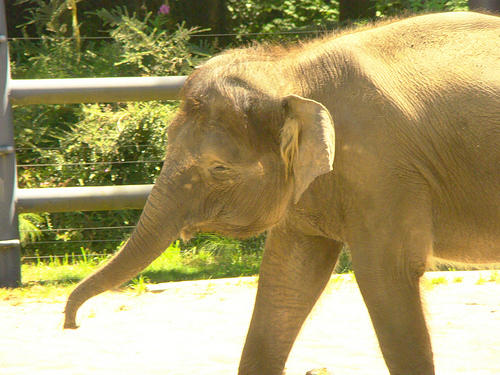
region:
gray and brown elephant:
[40, 20, 480, 370]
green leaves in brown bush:
[88, 110, 132, 135]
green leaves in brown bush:
[116, 126, 148, 146]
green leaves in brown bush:
[57, 220, 106, 249]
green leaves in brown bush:
[200, 248, 240, 268]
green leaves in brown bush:
[39, 243, 59, 256]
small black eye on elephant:
[198, 153, 239, 183]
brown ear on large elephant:
[264, 87, 347, 204]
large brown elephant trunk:
[60, 172, 185, 330]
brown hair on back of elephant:
[247, 39, 301, 64]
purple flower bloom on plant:
[153, 1, 173, 15]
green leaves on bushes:
[230, 0, 333, 27]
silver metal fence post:
[0, 30, 25, 298]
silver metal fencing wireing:
[14, 210, 102, 267]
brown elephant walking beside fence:
[59, 16, 492, 373]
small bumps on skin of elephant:
[394, 25, 449, 58]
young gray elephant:
[47, 14, 498, 374]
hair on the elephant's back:
[225, 10, 498, 60]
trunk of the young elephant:
[63, 194, 163, 332]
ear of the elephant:
[278, 93, 336, 200]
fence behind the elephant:
[3, 14, 388, 275]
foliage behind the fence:
[10, 2, 358, 271]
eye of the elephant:
[213, 160, 229, 172]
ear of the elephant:
[283, 94, 340, 194]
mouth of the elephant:
[176, 222, 209, 242]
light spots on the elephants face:
[170, 146, 265, 186]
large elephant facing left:
[49, 5, 498, 372]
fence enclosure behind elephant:
[1, 9, 345, 286]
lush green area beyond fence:
[4, 2, 499, 284]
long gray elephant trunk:
[55, 158, 194, 332]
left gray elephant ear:
[273, 93, 340, 209]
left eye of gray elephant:
[195, 151, 240, 182]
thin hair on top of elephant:
[142, 9, 471, 132]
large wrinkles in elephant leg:
[247, 237, 319, 374]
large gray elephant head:
[47, 46, 336, 341]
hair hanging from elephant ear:
[276, 111, 305, 182]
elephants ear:
[291, 95, 348, 190]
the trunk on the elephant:
[53, 276, 100, 332]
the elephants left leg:
[366, 285, 424, 371]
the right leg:
[244, 338, 282, 370]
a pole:
[48, 178, 130, 210]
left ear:
[204, 158, 239, 180]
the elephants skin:
[405, 23, 498, 100]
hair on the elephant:
[258, 39, 293, 60]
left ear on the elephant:
[287, 99, 332, 181]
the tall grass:
[43, 244, 83, 269]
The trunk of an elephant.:
[57, 213, 198, 333]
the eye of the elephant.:
[204, 150, 241, 179]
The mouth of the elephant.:
[174, 199, 241, 261]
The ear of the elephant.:
[272, 92, 359, 203]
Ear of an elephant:
[275, 90, 344, 213]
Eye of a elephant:
[207, 158, 234, 178]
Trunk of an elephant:
[49, 191, 199, 332]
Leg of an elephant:
[345, 243, 449, 373]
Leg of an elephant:
[224, 235, 348, 374]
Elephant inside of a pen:
[42, 9, 493, 371]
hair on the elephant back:
[239, 33, 367, 73]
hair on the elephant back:
[254, 45, 315, 65]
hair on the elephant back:
[297, 33, 344, 57]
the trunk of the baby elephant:
[63, 12, 498, 374]